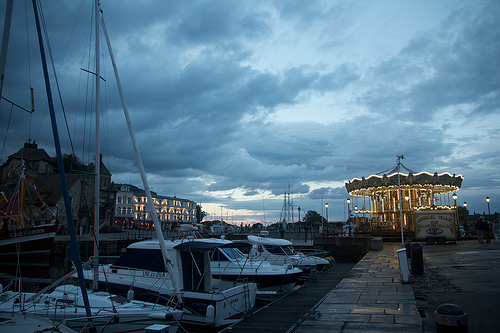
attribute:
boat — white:
[0, 280, 190, 331]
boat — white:
[71, 233, 258, 324]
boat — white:
[210, 236, 301, 282]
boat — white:
[0, 162, 60, 287]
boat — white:
[250, 233, 332, 270]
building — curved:
[108, 190, 205, 230]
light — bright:
[179, 204, 189, 215]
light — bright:
[172, 205, 182, 213]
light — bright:
[165, 205, 176, 215]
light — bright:
[159, 195, 171, 207]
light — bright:
[134, 203, 146, 213]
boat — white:
[242, 222, 329, 277]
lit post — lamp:
[320, 200, 337, 225]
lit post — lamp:
[341, 189, 361, 226]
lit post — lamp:
[400, 185, 415, 226]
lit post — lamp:
[447, 185, 463, 208]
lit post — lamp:
[476, 185, 493, 220]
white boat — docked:
[14, 264, 171, 329]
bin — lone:
[430, 296, 472, 331]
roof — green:
[345, 155, 462, 195]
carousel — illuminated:
[342, 152, 463, 239]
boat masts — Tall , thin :
[0, 0, 189, 316]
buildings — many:
[8, 142, 467, 249]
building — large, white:
[102, 185, 209, 232]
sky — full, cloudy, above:
[1, 2, 499, 232]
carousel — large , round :
[334, 160, 456, 253]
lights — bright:
[387, 162, 445, 184]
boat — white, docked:
[72, 231, 305, 288]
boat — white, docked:
[195, 221, 289, 283]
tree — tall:
[299, 209, 329, 240]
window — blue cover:
[119, 246, 167, 271]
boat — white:
[241, 229, 335, 278]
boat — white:
[173, 237, 303, 288]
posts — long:
[322, 207, 355, 234]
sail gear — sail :
[2, 3, 97, 323]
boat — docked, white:
[64, 222, 249, 332]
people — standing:
[444, 209, 499, 247]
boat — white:
[43, 295, 182, 329]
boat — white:
[192, 227, 322, 296]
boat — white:
[196, 213, 352, 290]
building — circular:
[341, 148, 474, 241]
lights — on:
[110, 189, 201, 224]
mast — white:
[3, 0, 186, 331]